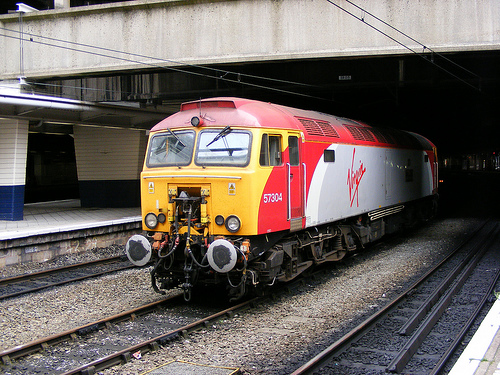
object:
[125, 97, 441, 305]
train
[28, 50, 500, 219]
tunnel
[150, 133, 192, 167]
windows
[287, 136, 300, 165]
windows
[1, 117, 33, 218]
supports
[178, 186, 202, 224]
opening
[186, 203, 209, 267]
tubing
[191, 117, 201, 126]
light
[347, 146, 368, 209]
name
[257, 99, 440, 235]
side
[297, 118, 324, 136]
vents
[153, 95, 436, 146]
roof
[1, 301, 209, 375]
rails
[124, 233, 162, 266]
bumper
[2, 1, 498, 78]
overpass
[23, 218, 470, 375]
gravel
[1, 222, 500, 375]
tracks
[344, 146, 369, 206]
logo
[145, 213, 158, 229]
headlights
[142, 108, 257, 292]
front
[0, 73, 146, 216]
building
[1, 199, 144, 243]
platform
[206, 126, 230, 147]
wipers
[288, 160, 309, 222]
railing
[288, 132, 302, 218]
door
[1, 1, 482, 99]
power lines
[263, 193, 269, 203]
number